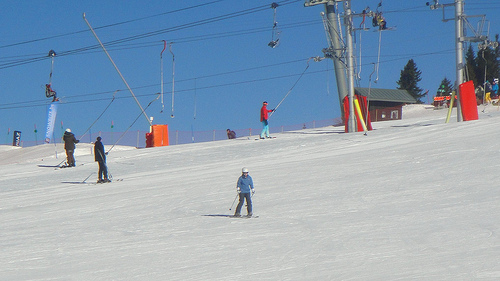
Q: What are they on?
A: Ski lift.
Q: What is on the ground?
A: Snow.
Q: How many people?
A: 5.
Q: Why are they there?
A: To ski.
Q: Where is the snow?
A: On the ground.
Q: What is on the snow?
A: People.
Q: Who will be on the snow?
A: People.